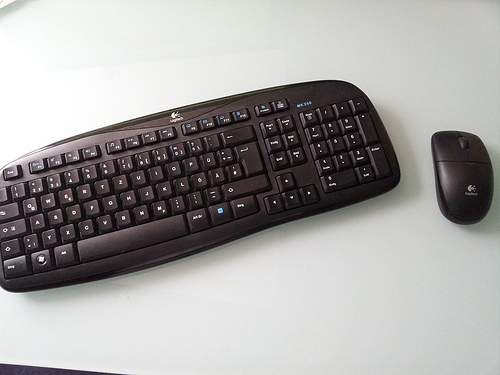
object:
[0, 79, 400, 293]
keyboard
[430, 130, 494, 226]
mouse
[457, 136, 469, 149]
wheel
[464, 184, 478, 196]
logo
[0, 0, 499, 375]
table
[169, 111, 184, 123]
logo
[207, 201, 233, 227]
key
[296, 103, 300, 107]
letters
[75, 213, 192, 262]
spacebar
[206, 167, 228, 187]
keys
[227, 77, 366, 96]
board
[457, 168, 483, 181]
black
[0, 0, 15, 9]
computer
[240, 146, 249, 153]
enter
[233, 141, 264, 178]
button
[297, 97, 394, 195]
pad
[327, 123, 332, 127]
numbers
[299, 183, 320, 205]
keys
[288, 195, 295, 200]
arrow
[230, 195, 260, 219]
button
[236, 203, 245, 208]
control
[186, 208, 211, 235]
button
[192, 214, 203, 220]
alt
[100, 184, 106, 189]
letters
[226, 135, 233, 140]
backspace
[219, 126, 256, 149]
button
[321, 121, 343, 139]
keys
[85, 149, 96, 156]
functions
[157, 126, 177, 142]
keys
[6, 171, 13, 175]
escape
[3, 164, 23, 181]
key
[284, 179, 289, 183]
arrows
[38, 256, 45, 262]
windows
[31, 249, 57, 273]
key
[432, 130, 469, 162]
button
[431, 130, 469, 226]
left